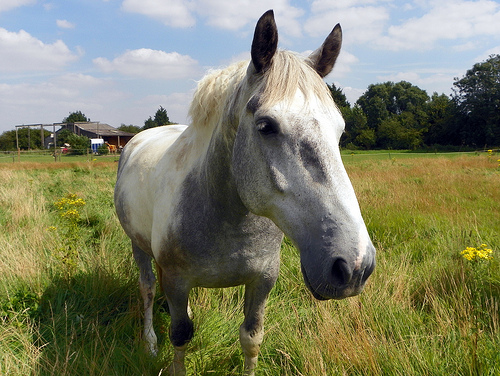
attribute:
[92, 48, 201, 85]
cloud — gray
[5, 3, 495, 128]
sky — blue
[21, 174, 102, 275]
grass — dry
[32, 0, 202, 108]
sky — cloudy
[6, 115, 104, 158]
structure — wooden